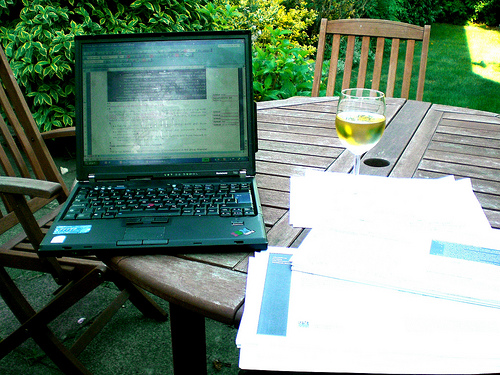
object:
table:
[95, 95, 500, 375]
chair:
[311, 17, 431, 100]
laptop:
[38, 32, 267, 253]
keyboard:
[63, 181, 255, 221]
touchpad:
[117, 225, 168, 247]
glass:
[334, 87, 385, 175]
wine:
[333, 113, 384, 148]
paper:
[235, 168, 500, 375]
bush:
[1, 0, 316, 132]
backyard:
[0, 0, 499, 374]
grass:
[310, 22, 500, 112]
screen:
[81, 39, 248, 165]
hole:
[363, 158, 389, 168]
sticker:
[49, 235, 67, 244]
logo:
[231, 226, 255, 237]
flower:
[276, 10, 283, 20]